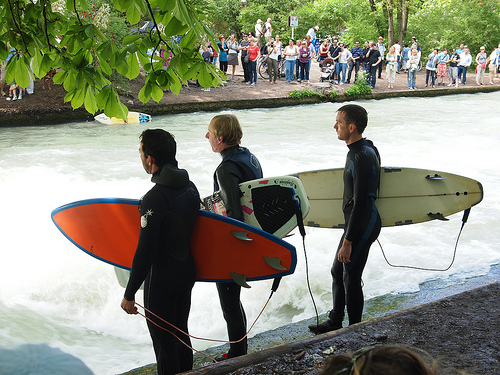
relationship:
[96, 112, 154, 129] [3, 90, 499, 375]
surf board in water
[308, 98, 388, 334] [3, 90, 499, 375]
surfer by water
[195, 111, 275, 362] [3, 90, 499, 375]
surfer by water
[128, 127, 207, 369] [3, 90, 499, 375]
surfer by water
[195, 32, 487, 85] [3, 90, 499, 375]
spectators by water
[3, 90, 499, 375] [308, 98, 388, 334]
water by surfer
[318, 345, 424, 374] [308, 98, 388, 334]
hair behind surfer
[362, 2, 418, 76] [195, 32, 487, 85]
tree behind spectators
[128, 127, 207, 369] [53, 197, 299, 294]
surfer holding surf board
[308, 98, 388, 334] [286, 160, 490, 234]
surfer has surf board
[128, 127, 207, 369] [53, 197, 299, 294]
surfer has surf board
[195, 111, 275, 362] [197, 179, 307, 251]
surfer has surf board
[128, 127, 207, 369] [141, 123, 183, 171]
surfer has hair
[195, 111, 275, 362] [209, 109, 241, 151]
surfer has hair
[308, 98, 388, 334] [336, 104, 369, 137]
surfer has hair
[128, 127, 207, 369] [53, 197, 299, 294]
surfer holds surf board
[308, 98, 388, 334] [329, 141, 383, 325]
surfer wears wetsuit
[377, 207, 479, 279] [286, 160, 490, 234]
cord on surf board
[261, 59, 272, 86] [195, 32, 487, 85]
tire near spectators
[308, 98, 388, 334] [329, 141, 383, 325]
surfer in wetsuit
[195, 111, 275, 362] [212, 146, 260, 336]
surfer in wetsuit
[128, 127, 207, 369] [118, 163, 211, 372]
surfer in wetsuit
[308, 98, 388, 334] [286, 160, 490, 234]
surfer holding surf board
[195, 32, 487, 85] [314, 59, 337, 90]
spectators have stroller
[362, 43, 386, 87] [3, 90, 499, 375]
man by water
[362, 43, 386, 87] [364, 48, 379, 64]
man has shirt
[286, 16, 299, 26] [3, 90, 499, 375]
sign by water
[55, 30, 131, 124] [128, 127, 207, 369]
leaves above surfer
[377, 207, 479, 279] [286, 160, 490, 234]
cord from surf board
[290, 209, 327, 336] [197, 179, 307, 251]
cord from surf board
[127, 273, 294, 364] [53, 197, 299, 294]
cord from surf board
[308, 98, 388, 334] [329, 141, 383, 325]
surfer wearing wetsuit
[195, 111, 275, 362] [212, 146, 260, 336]
surfer wearing wetsuit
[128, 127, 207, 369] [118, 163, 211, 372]
surfer wearing wetsuit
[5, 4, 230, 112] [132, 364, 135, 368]
branches hanging down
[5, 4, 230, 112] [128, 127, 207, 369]
branches near surfer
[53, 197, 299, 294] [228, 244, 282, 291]
surf board has fins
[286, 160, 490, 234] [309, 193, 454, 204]
surf board has line